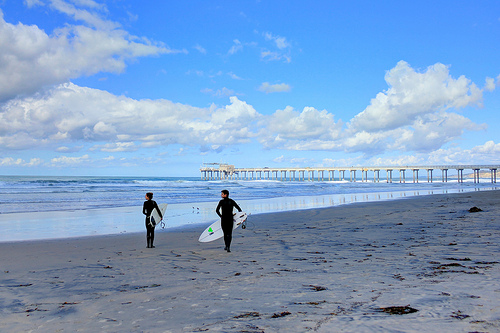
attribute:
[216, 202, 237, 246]
wetsuit — black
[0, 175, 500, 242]
ocean — blue, wavy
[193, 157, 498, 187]
pier — large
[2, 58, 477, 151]
cloud — white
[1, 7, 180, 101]
cloud — white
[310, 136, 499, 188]
cloud — white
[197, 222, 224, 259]
surfboard — white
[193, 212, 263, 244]
board — surfboard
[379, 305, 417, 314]
seaweed — dried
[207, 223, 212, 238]
sticker — neon green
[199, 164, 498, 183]
pier — very long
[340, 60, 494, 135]
cloud — thick, white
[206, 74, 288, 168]
cloud — thick, white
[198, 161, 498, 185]
pier — long, wooden, light-colored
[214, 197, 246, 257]
wetsuit — black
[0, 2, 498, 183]
sky — blue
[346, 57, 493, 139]
clouds — white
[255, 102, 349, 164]
clouds — white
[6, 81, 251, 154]
clouds — white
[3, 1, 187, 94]
clouds — white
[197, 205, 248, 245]
surfboard — white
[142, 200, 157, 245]
wetsuit — black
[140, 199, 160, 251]
wetsuit — black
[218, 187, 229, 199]
hair — black